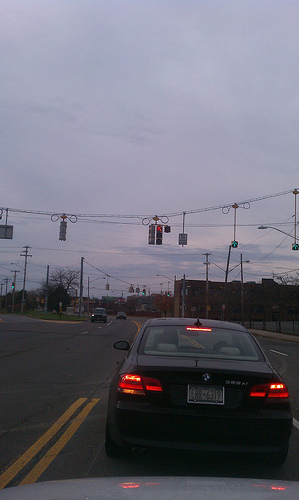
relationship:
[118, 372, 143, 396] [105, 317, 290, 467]
light on a car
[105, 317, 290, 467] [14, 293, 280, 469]
car on street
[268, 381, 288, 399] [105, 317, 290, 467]
tail light of car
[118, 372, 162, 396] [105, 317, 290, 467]
light of car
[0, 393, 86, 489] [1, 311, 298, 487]
lines on street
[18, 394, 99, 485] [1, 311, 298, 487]
lines on street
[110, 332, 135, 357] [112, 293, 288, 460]
mirror on car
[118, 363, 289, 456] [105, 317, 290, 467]
rear end of car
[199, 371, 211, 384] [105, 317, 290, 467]
bmw logo on car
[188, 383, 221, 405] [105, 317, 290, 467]
license plate on car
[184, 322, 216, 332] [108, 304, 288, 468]
light of car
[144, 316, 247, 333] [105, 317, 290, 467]
roof of car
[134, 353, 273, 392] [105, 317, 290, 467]
trunk of car